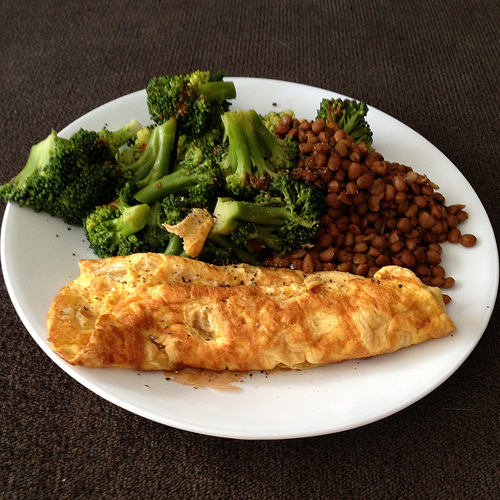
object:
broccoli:
[79, 194, 207, 263]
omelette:
[45, 250, 457, 372]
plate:
[0, 74, 499, 440]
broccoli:
[81, 201, 153, 255]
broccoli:
[1, 126, 120, 225]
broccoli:
[145, 67, 235, 140]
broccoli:
[212, 108, 300, 198]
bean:
[271, 113, 476, 303]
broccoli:
[119, 120, 227, 211]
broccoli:
[317, 97, 372, 141]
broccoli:
[206, 177, 320, 260]